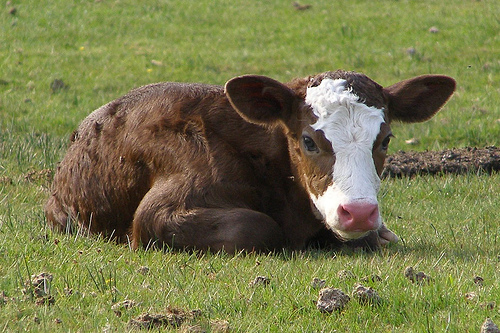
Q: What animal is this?
A: Cow.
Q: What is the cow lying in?
A: Grass.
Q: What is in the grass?
A: Rocks.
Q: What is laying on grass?
A: Cow.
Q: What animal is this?
A: Cow.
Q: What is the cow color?
A: White and brown.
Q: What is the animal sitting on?
A: Grass.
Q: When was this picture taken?
A: In the day.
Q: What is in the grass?
A: Lots of rocks.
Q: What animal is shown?
A: A cow.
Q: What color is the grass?
A: Green.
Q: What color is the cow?
A: Brown and white.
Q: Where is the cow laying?
A: The ground.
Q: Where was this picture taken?
A: A field.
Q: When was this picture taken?
A: Daytime.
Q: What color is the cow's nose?
A: Pink.